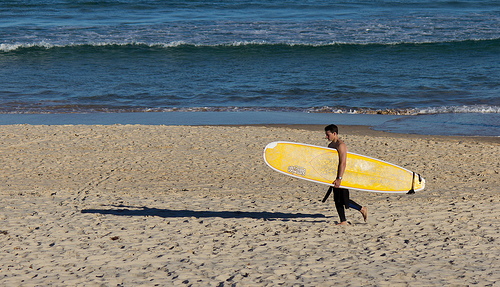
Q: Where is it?
A: This is at the beach.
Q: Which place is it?
A: It is a beach.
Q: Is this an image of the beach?
A: Yes, it is showing the beach.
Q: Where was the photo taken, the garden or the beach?
A: It was taken at the beach.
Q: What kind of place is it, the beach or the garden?
A: It is the beach.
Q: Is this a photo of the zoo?
A: No, the picture is showing the beach.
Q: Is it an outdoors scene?
A: Yes, it is outdoors.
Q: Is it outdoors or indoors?
A: It is outdoors.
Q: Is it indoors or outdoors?
A: It is outdoors.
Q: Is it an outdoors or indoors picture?
A: It is outdoors.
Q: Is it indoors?
A: No, it is outdoors.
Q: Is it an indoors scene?
A: No, it is outdoors.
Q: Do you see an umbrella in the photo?
A: No, there are no umbrellas.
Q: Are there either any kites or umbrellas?
A: No, there are no umbrellas or kites.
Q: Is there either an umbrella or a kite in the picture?
A: No, there are no umbrellas or kites.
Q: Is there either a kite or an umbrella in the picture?
A: No, there are no umbrellas or kites.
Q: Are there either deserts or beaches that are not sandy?
A: No, there is a beach but it is sandy.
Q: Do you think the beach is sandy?
A: Yes, the beach is sandy.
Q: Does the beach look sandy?
A: Yes, the beach is sandy.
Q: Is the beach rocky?
A: No, the beach is sandy.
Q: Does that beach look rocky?
A: No, the beach is sandy.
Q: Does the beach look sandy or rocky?
A: The beach is sandy.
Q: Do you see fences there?
A: No, there are no fences.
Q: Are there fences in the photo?
A: No, there are no fences.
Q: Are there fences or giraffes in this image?
A: No, there are no fences or giraffes.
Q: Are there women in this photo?
A: No, there are no women.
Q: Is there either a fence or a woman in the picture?
A: No, there are no women or fences.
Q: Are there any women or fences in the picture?
A: No, there are no women or fences.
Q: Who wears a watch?
A: The man wears a watch.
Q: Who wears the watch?
A: The man wears a watch.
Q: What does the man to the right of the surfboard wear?
A: The man wears a watch.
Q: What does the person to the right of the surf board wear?
A: The man wears a watch.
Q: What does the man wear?
A: The man wears a watch.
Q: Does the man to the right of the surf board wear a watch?
A: Yes, the man wears a watch.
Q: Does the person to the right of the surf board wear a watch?
A: Yes, the man wears a watch.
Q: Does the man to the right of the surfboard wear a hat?
A: No, the man wears a watch.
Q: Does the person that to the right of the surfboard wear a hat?
A: No, the man wears a watch.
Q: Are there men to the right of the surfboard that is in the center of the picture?
A: Yes, there is a man to the right of the surfboard.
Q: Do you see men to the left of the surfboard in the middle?
A: No, the man is to the right of the surfboard.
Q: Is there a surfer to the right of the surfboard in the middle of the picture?
A: No, there is a man to the right of the surfboard.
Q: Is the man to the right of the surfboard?
A: Yes, the man is to the right of the surfboard.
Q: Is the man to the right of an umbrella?
A: No, the man is to the right of the surfboard.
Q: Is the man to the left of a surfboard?
A: No, the man is to the right of a surfboard.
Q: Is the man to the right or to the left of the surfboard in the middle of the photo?
A: The man is to the right of the surfboard.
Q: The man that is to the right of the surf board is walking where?
A: The man is walking on the beach.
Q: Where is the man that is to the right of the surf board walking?
A: The man is walking on the beach.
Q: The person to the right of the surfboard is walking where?
A: The man is walking on the beach.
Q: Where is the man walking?
A: The man is walking on the beach.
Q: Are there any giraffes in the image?
A: No, there are no giraffes.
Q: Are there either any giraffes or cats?
A: No, there are no giraffes or cats.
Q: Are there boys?
A: No, there are no boys.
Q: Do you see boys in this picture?
A: No, there are no boys.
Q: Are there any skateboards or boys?
A: No, there are no boys or skateboards.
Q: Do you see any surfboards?
A: Yes, there is a surfboard.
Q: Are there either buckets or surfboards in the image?
A: Yes, there is a surfboard.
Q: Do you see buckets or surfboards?
A: Yes, there is a surfboard.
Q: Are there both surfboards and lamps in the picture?
A: No, there is a surfboard but no lamps.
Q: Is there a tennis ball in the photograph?
A: No, there are no tennis balls.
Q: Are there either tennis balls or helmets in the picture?
A: No, there are no tennis balls or helmets.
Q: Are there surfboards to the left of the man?
A: Yes, there is a surfboard to the left of the man.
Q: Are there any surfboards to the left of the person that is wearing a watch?
A: Yes, there is a surfboard to the left of the man.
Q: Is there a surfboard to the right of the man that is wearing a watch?
A: No, the surfboard is to the left of the man.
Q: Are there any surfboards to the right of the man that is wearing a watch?
A: No, the surfboard is to the left of the man.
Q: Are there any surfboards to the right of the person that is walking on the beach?
A: No, the surfboard is to the left of the man.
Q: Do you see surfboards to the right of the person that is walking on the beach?
A: No, the surfboard is to the left of the man.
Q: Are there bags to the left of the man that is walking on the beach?
A: No, there is a surfboard to the left of the man.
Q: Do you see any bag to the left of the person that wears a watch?
A: No, there is a surfboard to the left of the man.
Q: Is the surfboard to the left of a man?
A: Yes, the surfboard is to the left of a man.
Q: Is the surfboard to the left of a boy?
A: No, the surfboard is to the left of a man.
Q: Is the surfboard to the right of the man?
A: No, the surfboard is to the left of the man.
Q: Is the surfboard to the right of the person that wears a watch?
A: No, the surfboard is to the left of the man.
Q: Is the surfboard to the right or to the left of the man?
A: The surfboard is to the left of the man.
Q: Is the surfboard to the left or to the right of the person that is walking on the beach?
A: The surfboard is to the left of the man.